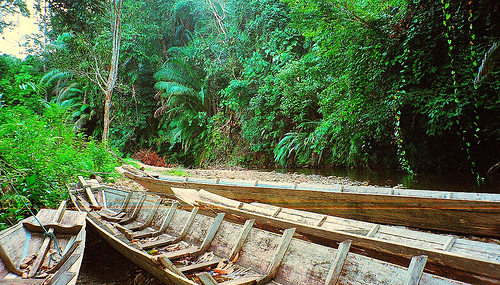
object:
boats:
[167, 185, 500, 285]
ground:
[75, 231, 162, 284]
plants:
[89, 136, 118, 183]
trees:
[60, 0, 165, 151]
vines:
[462, 0, 484, 148]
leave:
[453, 91, 459, 94]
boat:
[0, 205, 89, 285]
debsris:
[20, 269, 28, 279]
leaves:
[136, 36, 143, 40]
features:
[189, 0, 234, 44]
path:
[120, 158, 280, 175]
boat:
[113, 163, 500, 238]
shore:
[243, 169, 376, 187]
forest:
[0, 0, 497, 224]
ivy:
[390, 88, 419, 178]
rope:
[1, 169, 49, 232]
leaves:
[212, 268, 228, 278]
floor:
[176, 257, 261, 285]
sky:
[0, 0, 56, 62]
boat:
[64, 174, 468, 285]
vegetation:
[0, 105, 44, 202]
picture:
[0, 0, 500, 285]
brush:
[287, 0, 392, 171]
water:
[256, 166, 500, 194]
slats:
[158, 202, 179, 232]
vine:
[436, 0, 485, 183]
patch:
[131, 148, 180, 168]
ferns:
[276, 134, 296, 146]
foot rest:
[21, 208, 87, 234]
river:
[252, 166, 500, 195]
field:
[0, 164, 495, 285]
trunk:
[99, 95, 113, 146]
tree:
[379, 0, 496, 176]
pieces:
[129, 194, 147, 219]